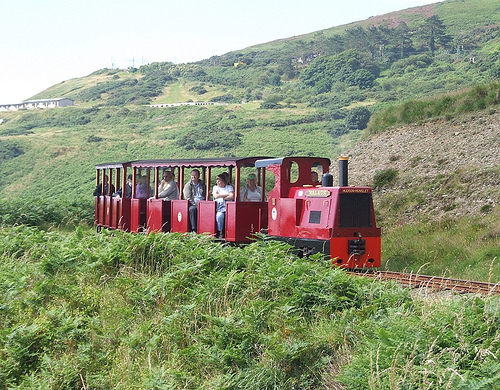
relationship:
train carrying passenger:
[92, 155, 381, 274] [210, 173, 234, 216]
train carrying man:
[92, 155, 381, 274] [182, 168, 206, 232]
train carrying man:
[92, 155, 381, 274] [149, 170, 180, 203]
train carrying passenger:
[92, 155, 381, 274] [127, 166, 152, 197]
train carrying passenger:
[92, 155, 381, 274] [90, 169, 114, 195]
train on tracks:
[92, 155, 381, 274] [286, 251, 494, 303]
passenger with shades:
[211, 174, 234, 238] [212, 174, 224, 184]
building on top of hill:
[1, 96, 66, 118] [12, 82, 219, 152]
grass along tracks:
[6, 237, 488, 388] [344, 271, 500, 296]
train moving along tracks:
[92, 150, 384, 274] [381, 268, 498, 293]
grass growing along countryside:
[6, 237, 488, 388] [12, 54, 499, 147]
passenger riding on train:
[93, 174, 115, 197] [92, 150, 384, 274]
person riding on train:
[126, 167, 155, 201] [92, 150, 384, 274]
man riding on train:
[149, 170, 180, 203] [92, 150, 384, 274]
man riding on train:
[182, 168, 206, 232] [92, 150, 384, 274]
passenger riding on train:
[211, 174, 234, 238] [92, 150, 384, 274]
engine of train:
[249, 149, 386, 270] [82, 145, 391, 290]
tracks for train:
[346, 267, 499, 294] [92, 150, 384, 274]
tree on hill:
[254, 86, 283, 105] [186, 0, 500, 64]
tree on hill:
[279, 74, 309, 104] [186, 0, 500, 64]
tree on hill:
[344, 65, 375, 90] [186, 0, 500, 64]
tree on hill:
[391, 20, 415, 50] [186, 0, 500, 64]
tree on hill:
[414, 13, 444, 54] [186, 0, 500, 64]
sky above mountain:
[36, 15, 190, 52] [282, 1, 497, 114]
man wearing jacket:
[177, 167, 210, 222] [179, 175, 209, 205]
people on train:
[100, 168, 260, 232] [67, 153, 392, 278]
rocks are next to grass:
[340, 116, 496, 229] [6, 237, 488, 388]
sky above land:
[0, 0, 444, 105] [1, 1, 499, 387]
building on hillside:
[0, 96, 75, 113] [0, 0, 497, 286]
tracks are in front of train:
[347, 262, 498, 307] [92, 150, 384, 274]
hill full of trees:
[209, 39, 475, 140] [90, 34, 481, 123]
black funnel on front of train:
[336, 155, 348, 186] [92, 150, 384, 274]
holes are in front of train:
[329, 252, 383, 272] [92, 150, 384, 274]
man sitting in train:
[149, 170, 180, 203] [82, 145, 391, 290]